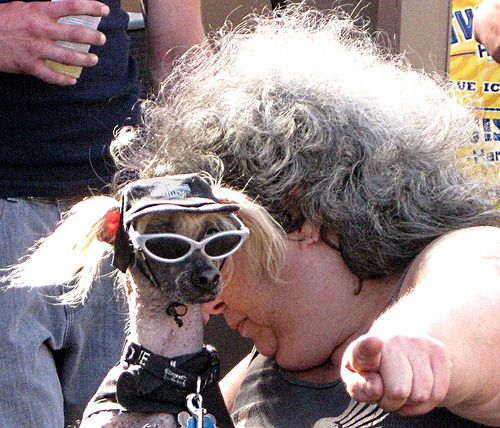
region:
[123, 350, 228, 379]
collar on dog neck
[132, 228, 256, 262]
sunglasses on dog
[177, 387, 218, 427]
tag on collar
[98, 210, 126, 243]
barrett on dog fur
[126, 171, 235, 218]
hat on dog's head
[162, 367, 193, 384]
design on collar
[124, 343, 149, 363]
design on collar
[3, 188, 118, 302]
ponytail on the dog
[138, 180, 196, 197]
design on dog hat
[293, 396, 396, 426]
design on woman's shirt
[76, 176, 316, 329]
a dog in sunglasses and hat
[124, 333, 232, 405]
a black dog collar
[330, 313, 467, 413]
a fat hand pointing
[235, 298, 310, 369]
a large double chin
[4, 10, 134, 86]
a hand holding a cup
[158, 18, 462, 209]
grey hair of woman messy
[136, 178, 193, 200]
writing on the dogs hat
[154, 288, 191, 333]
a chin strap for the dog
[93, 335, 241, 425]
a dog with a cape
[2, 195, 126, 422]
blue jeans behind the dog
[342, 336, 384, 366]
finger of a white woman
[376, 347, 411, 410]
finger of a white woman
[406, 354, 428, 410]
finger of a white woman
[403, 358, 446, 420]
finger of a white woman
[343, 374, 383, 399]
finger of a white woman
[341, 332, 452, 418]
hand of a white woman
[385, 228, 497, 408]
arm of a white woman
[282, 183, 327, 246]
ear of a white woman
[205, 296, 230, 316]
nose of a white woman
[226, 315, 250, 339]
mouth of a white woman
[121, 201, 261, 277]
dog wearing sunglasses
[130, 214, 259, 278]
small white sunglasses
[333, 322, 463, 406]
hand is pointing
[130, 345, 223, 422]
black collar with blue metal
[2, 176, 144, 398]
person is wearing jeans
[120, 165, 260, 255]
dog is wearing black hat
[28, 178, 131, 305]
dogs hair is outward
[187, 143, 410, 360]
woman with eyes hidden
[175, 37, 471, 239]
woman with unruly grey hair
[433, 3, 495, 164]
yellow sign with blue lettering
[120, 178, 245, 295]
dog wearing sunglasses and a hat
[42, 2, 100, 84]
plastic cup of beer in a man's hand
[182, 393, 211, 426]
clip attached to the dog's collar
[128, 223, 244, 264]
white sunglasses on a dog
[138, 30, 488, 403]
gray haired woman pointing her finger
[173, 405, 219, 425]
tags on the dog's collar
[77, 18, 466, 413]
woman and a dog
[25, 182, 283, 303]
dog wearing sunglasses and a black hat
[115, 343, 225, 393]
collar around the dog's neck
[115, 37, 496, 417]
woman wearing a gray tank top